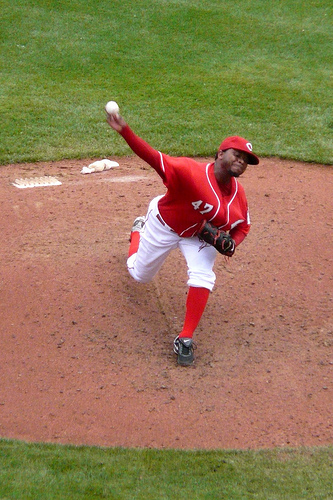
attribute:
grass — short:
[1, 0, 332, 166]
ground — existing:
[1, 0, 333, 500]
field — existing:
[1, 1, 333, 500]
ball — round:
[105, 99, 119, 117]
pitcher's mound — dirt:
[1, 155, 333, 449]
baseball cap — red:
[217, 134, 259, 165]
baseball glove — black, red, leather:
[195, 219, 235, 257]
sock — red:
[177, 286, 211, 341]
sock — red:
[126, 230, 140, 259]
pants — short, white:
[125, 193, 220, 292]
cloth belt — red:
[156, 213, 177, 234]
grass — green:
[0, 436, 333, 499]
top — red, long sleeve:
[156, 150, 251, 247]